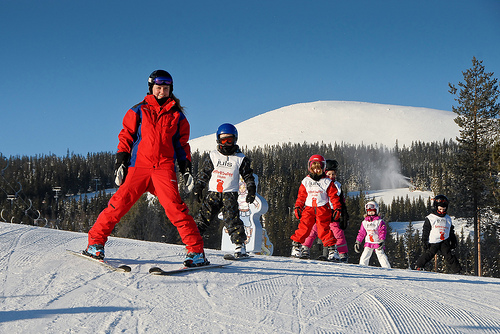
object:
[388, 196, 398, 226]
tree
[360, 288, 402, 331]
tracks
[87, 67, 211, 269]
skier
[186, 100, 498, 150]
hillside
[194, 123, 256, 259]
child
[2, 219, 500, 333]
slope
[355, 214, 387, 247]
coat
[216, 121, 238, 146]
helmet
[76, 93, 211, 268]
suit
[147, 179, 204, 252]
leg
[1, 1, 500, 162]
sky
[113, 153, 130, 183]
glove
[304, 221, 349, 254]
pink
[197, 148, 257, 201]
black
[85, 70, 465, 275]
group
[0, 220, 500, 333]
ground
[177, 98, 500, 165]
mountain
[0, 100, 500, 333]
snow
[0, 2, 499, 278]
background